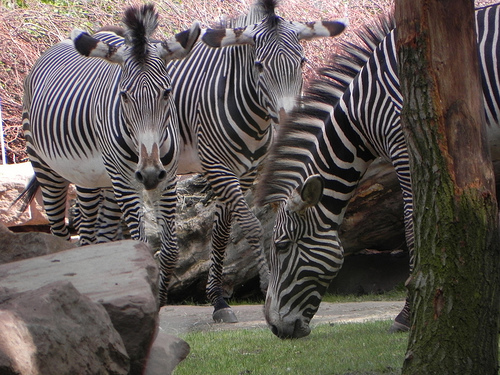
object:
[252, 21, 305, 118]
zebra's face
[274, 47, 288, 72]
markings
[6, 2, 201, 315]
zebra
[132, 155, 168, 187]
nose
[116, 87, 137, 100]
eyes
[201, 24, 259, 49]
ears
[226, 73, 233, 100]
hair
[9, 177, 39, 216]
tail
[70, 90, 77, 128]
stripes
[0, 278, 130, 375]
rocks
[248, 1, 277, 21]
hair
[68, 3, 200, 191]
head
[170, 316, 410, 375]
grass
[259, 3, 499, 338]
zebras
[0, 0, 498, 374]
picture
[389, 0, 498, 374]
tree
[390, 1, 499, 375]
tree trunk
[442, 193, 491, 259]
moss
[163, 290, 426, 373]
ground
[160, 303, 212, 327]
stone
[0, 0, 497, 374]
park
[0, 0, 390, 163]
forest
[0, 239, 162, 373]
stones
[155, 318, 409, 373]
area